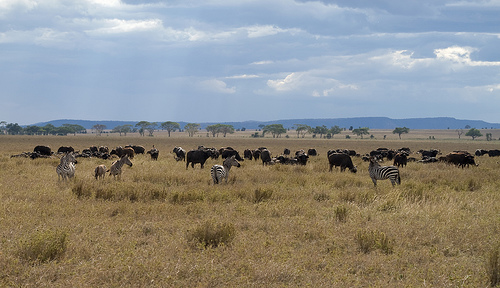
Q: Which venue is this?
A: This is a field.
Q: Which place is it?
A: It is a field.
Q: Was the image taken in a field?
A: Yes, it was taken in a field.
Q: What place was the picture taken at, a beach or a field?
A: It was taken at a field.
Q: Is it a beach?
A: No, it is a field.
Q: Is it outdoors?
A: Yes, it is outdoors.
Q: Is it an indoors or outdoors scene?
A: It is outdoors.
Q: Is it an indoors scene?
A: No, it is outdoors.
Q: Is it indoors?
A: No, it is outdoors.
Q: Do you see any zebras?
A: Yes, there are zebras.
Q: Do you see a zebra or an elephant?
A: Yes, there are zebras.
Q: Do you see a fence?
A: No, there are no fences.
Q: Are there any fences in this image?
A: No, there are no fences.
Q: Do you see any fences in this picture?
A: No, there are no fences.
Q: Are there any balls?
A: No, there are no balls.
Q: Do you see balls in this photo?
A: No, there are no balls.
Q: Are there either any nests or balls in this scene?
A: No, there are no balls or nests.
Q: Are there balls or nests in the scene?
A: No, there are no balls or nests.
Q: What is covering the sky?
A: The clouds are covering the sky.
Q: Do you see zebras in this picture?
A: Yes, there is a zebra.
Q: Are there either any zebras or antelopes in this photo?
A: Yes, there is a zebra.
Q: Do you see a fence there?
A: No, there are no fences.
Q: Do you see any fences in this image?
A: No, there are no fences.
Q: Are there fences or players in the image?
A: No, there are no fences or players.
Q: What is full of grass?
A: The field is full of grass.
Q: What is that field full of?
A: The field is full of grass.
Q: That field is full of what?
A: The field is full of grass.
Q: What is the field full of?
A: The field is full of grass.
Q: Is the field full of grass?
A: Yes, the field is full of grass.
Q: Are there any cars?
A: No, there are no cars.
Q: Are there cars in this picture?
A: No, there are no cars.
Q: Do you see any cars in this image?
A: No, there are no cars.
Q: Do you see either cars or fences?
A: No, there are no cars or fences.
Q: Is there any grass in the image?
A: Yes, there is grass.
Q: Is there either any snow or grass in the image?
A: Yes, there is grass.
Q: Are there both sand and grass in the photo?
A: No, there is grass but no sand.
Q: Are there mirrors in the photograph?
A: No, there are no mirrors.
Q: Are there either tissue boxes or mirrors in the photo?
A: No, there are no mirrors or tissue boxes.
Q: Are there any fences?
A: No, there are no fences.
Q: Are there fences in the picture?
A: No, there are no fences.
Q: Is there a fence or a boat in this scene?
A: No, there are no fences or boats.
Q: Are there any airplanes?
A: No, there are no airplanes.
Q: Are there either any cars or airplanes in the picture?
A: No, there are no airplanes or cars.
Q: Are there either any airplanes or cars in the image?
A: No, there are no airplanes or cars.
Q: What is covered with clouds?
A: The sky is covered with clouds.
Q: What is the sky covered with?
A: The sky is covered with clouds.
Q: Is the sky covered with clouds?
A: Yes, the sky is covered with clouds.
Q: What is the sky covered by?
A: The sky is covered by the clouds.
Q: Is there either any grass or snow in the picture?
A: Yes, there is grass.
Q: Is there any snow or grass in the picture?
A: Yes, there is grass.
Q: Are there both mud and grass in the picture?
A: No, there is grass but no mud.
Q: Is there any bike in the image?
A: No, there are no bikes.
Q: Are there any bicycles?
A: No, there are no bicycles.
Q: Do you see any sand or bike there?
A: No, there are no bikes or sand.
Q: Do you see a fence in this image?
A: No, there are no fences.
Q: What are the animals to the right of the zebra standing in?
A: The animals are standing in the grass.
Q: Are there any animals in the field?
A: Yes, there are animals in the field.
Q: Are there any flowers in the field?
A: No, there are animals in the field.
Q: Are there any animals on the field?
A: Yes, there are animals on the field.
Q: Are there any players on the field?
A: No, there are animals on the field.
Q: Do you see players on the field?
A: No, there are animals on the field.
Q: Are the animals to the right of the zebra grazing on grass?
A: Yes, the animals are grazing on grass.